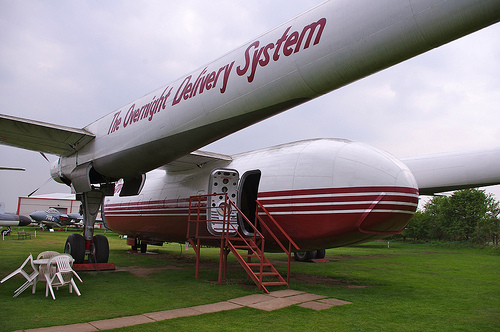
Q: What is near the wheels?
A: Chairs.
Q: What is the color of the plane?
A: White and red.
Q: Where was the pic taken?
A: In the field.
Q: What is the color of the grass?
A: Green.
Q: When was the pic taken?
A: During the day.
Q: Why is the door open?
A: To let people in.